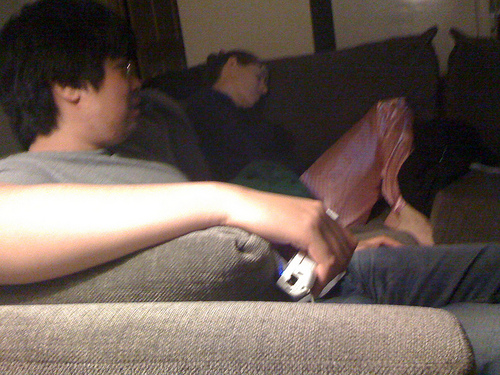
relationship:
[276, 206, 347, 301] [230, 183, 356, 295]
controller in hand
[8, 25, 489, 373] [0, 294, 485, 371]
couch has arm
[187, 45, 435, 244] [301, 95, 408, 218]
woman has pants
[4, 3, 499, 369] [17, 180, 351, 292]
man has arm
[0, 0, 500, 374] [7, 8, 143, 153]
man has head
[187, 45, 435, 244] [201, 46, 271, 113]
woman has head